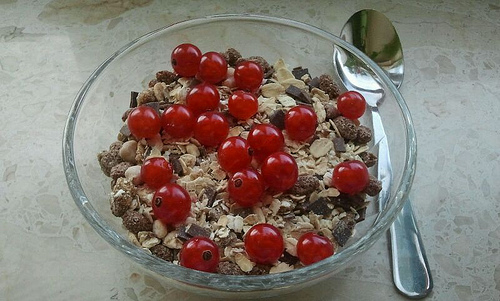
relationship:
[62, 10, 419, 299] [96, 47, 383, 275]
bowl filled with granola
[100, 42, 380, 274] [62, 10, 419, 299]
cereal in bowl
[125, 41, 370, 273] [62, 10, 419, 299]
cherries in bowl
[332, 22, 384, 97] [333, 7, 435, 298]
reflection on spoon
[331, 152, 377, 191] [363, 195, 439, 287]
cherry near silver spoon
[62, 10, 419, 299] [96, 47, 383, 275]
bowl has granola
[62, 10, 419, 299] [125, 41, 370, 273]
bowl has cherries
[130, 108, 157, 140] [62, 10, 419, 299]
cherry in bowl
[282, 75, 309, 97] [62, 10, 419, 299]
chocolate in bowl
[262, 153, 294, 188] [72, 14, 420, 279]
cherries in bowl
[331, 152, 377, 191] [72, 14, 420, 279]
cherry in bowl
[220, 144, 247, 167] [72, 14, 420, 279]
cherries in bowl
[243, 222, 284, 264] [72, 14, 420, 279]
cherry in bowl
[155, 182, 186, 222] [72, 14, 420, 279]
cherries in bowl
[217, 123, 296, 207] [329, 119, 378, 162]
red berries atop cereal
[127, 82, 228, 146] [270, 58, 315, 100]
red berries atop cereal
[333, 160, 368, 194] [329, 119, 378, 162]
red berries atop cereal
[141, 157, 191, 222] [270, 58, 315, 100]
red berries atop cereal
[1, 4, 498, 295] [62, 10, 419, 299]
white counter under bowl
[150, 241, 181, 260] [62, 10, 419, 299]
raisins in bowl